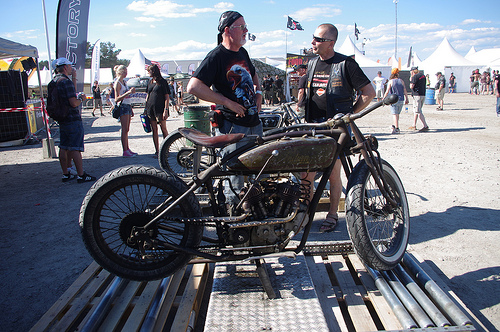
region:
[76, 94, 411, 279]
a motorcycle with a vintage appearance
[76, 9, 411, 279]
two men standing behind motorcycle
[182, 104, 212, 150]
a green metal drum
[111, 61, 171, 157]
two people turned towards each other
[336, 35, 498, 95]
pointed white canopy tops in the distance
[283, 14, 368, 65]
flags flying in the breeze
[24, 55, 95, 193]
man standing in a shaded area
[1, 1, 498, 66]
clouds in the blue sky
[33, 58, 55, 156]
cement base for a metal pole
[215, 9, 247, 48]
cloth tied at the back of man's head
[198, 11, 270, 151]
this is a man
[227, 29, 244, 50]
the man is light skinned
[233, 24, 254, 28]
this is a spectacle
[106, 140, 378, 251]
this is a motorbike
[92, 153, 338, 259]
the motorbike is parked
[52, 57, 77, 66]
this is a cap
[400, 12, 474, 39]
this is the sky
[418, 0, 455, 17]
the sky is blue in color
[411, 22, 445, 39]
these are the clouds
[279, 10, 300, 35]
this is a flag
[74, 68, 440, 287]
a parked motorcycle near two men.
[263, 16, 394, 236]
a man standing near a motorcycle.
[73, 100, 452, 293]
a motorcycle on a metal structure.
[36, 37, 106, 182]
A man standing in a crowd.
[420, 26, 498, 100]
a large white tent.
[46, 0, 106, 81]
a large banner near a crowd.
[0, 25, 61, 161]
a ten held up with poles.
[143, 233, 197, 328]
a large metal pole.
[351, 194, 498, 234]
a shadow cast on the ground.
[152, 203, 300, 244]
a section of chain on a motorcycle.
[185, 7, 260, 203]
man wearing bandana talking to man in black vest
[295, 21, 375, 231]
man in black vest and tshirt standing on beach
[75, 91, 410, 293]
black antique motorcycle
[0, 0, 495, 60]
blue cloudy sky above beach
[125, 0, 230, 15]
white fluffy cloud in the sky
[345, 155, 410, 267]
black rubber front tire on motorcycle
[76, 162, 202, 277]
rear black rubber tire on motorcycle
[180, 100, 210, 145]
green painted trash can behind man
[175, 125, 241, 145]
red seat on antique motorcycle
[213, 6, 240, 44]
black bandana on mans head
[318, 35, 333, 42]
this is a spectacle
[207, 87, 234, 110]
the man is light skinned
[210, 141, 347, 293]
the motorbike is parked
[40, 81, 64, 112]
this is a bag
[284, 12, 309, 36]
this is a flag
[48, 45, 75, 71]
this is a cap